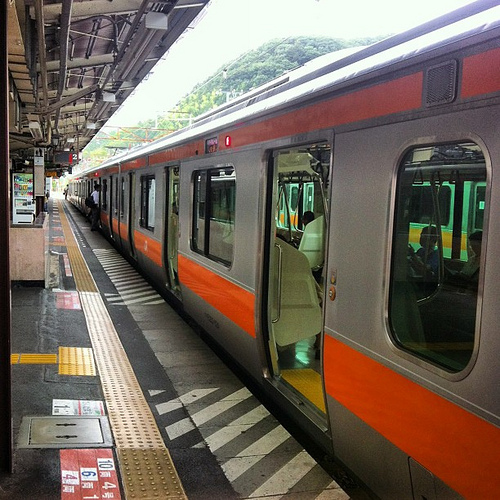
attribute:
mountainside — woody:
[84, 27, 397, 149]